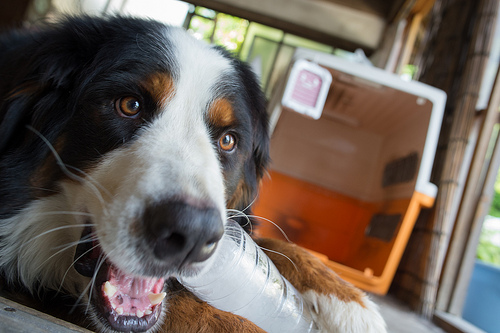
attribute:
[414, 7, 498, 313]
curtain — open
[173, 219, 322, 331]
bottle — Plastic 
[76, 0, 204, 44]
building — side